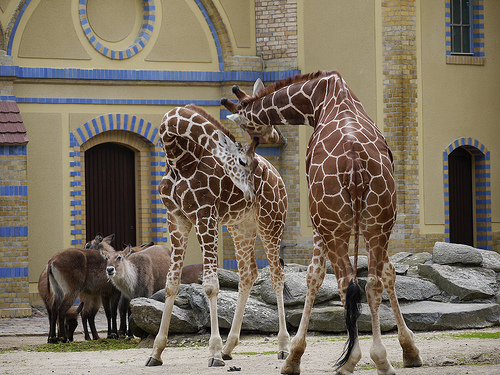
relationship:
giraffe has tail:
[219, 57, 431, 375] [332, 166, 364, 373]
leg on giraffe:
[140, 225, 187, 366] [141, 100, 295, 369]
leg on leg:
[192, 230, 232, 373] [140, 225, 187, 366]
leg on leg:
[222, 221, 263, 359] [192, 230, 232, 373]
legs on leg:
[257, 210, 293, 363] [222, 221, 263, 359]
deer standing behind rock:
[99, 242, 175, 337] [130, 294, 198, 338]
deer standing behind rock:
[99, 242, 175, 337] [144, 278, 195, 311]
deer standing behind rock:
[99, 242, 175, 337] [185, 277, 285, 337]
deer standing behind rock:
[99, 242, 175, 337] [196, 263, 244, 288]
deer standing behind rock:
[99, 242, 175, 337] [261, 267, 341, 307]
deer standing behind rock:
[40, 239, 156, 339] [130, 294, 198, 338]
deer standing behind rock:
[40, 239, 156, 339] [144, 278, 195, 311]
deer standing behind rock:
[40, 239, 156, 339] [185, 277, 285, 337]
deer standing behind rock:
[40, 239, 156, 339] [196, 263, 244, 288]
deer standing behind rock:
[40, 239, 156, 339] [261, 267, 341, 307]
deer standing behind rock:
[46, 240, 157, 344] [130, 294, 198, 338]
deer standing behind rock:
[46, 240, 157, 344] [144, 278, 195, 311]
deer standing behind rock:
[46, 240, 157, 344] [185, 277, 285, 337]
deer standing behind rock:
[46, 240, 157, 344] [196, 263, 244, 288]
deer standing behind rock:
[46, 240, 157, 344] [261, 267, 341, 307]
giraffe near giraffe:
[215, 57, 452, 363] [141, 100, 295, 369]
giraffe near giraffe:
[141, 100, 295, 369] [215, 57, 452, 363]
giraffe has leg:
[141, 100, 295, 369] [145, 210, 191, 366]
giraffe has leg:
[141, 100, 295, 369] [194, 215, 225, 365]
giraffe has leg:
[141, 100, 295, 369] [221, 212, 257, 358]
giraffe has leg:
[141, 100, 295, 369] [255, 202, 291, 359]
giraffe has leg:
[219, 57, 431, 375] [319, 229, 356, 331]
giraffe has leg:
[219, 57, 431, 375] [353, 233, 386, 352]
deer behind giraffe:
[99, 242, 175, 337] [219, 57, 431, 375]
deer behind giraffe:
[99, 242, 175, 337] [141, 100, 295, 369]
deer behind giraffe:
[38, 229, 117, 341] [219, 57, 431, 375]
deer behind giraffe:
[38, 229, 117, 341] [141, 100, 295, 369]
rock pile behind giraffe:
[133, 237, 498, 336] [228, 62, 435, 373]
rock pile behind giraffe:
[133, 237, 498, 336] [141, 100, 295, 369]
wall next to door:
[0, 140, 30, 318] [79, 141, 141, 256]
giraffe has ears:
[219, 57, 431, 375] [226, 79, 262, 124]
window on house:
[444, 4, 480, 54] [0, 0, 500, 320]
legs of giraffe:
[165, 210, 290, 350] [141, 100, 295, 369]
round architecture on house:
[76, 2, 156, 59] [0, 0, 500, 320]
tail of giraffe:
[329, 180, 374, 374] [219, 57, 431, 375]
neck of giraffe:
[163, 113, 232, 159] [144, 94, 324, 373]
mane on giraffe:
[246, 71, 322, 97] [219, 57, 431, 375]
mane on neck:
[246, 71, 322, 97] [271, 76, 323, 128]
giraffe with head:
[141, 100, 295, 369] [202, 115, 261, 212]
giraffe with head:
[219, 57, 431, 375] [209, 119, 258, 211]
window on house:
[449, 0, 475, 57] [0, 0, 500, 320]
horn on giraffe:
[219, 96, 243, 118] [219, 57, 431, 375]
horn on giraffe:
[226, 79, 253, 104] [219, 57, 431, 375]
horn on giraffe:
[236, 134, 263, 161] [219, 57, 431, 375]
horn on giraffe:
[219, 96, 243, 118] [141, 100, 295, 369]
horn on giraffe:
[226, 79, 253, 104] [141, 100, 295, 369]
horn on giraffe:
[236, 134, 263, 161] [141, 100, 295, 369]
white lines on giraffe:
[336, 110, 369, 202] [219, 57, 431, 375]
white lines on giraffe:
[336, 110, 369, 202] [141, 100, 295, 369]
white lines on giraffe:
[179, 147, 224, 206] [219, 57, 431, 375]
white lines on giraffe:
[179, 147, 224, 206] [141, 100, 295, 369]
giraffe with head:
[219, 57, 431, 375] [228, 81, 271, 205]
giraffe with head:
[141, 100, 295, 369] [228, 81, 271, 205]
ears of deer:
[96, 241, 131, 255] [100, 237, 165, 298]